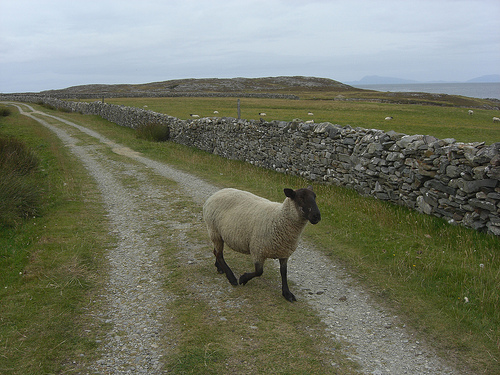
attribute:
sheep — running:
[202, 189, 318, 301]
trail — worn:
[74, 132, 121, 169]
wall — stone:
[368, 144, 444, 192]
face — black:
[294, 188, 321, 222]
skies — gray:
[175, 10, 267, 51]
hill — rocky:
[237, 76, 333, 95]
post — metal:
[235, 98, 242, 118]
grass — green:
[20, 292, 71, 336]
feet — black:
[228, 275, 249, 287]